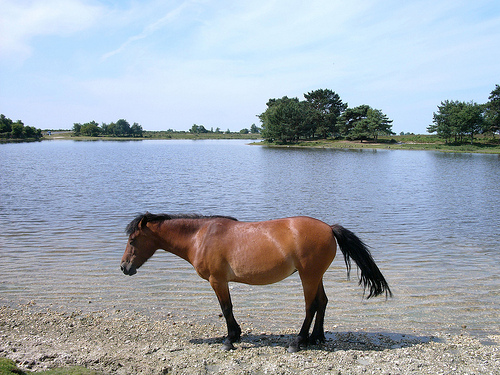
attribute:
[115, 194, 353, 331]
horse — brown, small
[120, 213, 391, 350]
horse — small, brown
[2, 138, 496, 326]
water — clear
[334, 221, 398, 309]
tail — black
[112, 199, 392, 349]
horse — small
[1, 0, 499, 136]
sky — blue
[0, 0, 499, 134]
clouds — thin